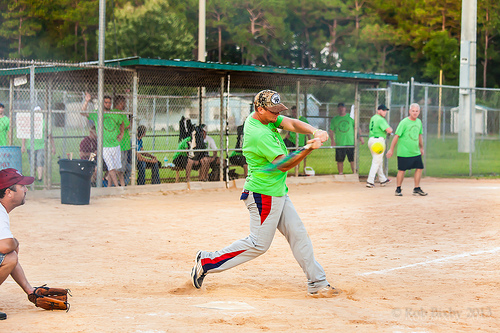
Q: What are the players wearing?
A: Green shirts.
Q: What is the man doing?
A: Swinging a baseball bat.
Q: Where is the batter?
A: At home base.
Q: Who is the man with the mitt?
A: The catcher.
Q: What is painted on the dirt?
A: White lines.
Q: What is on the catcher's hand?
A: A mitt.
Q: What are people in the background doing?
A: Watching.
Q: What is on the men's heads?
A: Hats.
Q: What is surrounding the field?
A: A fence.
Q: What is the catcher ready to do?
A: Catch the ball.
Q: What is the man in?
A: Green shirt.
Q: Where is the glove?
A: On ground.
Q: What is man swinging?
A: Bat.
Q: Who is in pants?
A: Batter.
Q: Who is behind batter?
A: Catcher.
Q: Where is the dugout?
A: By field.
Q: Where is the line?
A: On ground.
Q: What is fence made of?
A: Metal.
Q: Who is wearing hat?
A: A man.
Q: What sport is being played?
A: Baseball.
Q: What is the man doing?
A: Swinging the bat.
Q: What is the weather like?
A: Sunny.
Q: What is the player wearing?
A: Green shirt.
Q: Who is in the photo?
A: Some ball players.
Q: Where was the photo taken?
A: On the ball field.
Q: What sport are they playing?
A: Baseball.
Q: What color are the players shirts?
A: Green.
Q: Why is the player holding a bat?
A: To hit the ball.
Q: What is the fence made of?
A: Metal.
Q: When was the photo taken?
A: During the day.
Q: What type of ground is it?
A: Dirt.